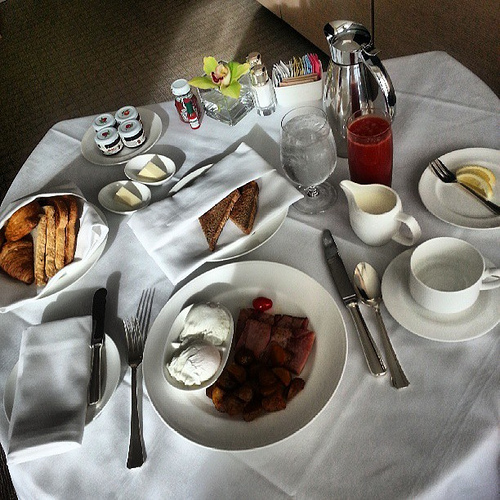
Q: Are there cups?
A: Yes, there is a cup.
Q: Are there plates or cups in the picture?
A: Yes, there is a cup.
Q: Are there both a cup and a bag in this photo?
A: No, there is a cup but no bags.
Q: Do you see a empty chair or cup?
A: Yes, there is an empty cup.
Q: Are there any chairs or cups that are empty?
A: Yes, the cup is empty.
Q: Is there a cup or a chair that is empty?
A: Yes, the cup is empty.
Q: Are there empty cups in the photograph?
A: Yes, there is an empty cup.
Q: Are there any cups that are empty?
A: Yes, there is an empty cup.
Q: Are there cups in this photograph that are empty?
A: Yes, there is a cup that is empty.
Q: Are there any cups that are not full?
A: Yes, there is a empty cup.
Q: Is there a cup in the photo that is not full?
A: Yes, there is a empty cup.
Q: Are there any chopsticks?
A: No, there are no chopsticks.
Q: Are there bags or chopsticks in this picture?
A: No, there are no chopsticks or bags.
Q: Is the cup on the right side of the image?
A: Yes, the cup is on the right of the image.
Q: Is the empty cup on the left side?
A: No, the cup is on the right of the image.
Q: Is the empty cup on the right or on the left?
A: The cup is on the right of the image.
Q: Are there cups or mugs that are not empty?
A: No, there is a cup but it is empty.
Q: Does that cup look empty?
A: Yes, the cup is empty.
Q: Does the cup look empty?
A: Yes, the cup is empty.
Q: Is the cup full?
A: No, the cup is empty.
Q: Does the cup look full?
A: No, the cup is empty.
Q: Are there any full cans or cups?
A: No, there is a cup but it is empty.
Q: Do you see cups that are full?
A: No, there is a cup but it is empty.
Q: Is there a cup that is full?
A: No, there is a cup but it is empty.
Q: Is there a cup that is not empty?
A: No, there is a cup but it is empty.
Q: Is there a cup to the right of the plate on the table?
A: Yes, there is a cup to the right of the plate.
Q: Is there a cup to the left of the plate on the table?
A: No, the cup is to the right of the plate.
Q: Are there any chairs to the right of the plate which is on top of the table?
A: No, there is a cup to the right of the plate.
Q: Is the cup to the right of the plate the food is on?
A: Yes, the cup is to the right of the plate.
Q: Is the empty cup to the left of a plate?
A: No, the cup is to the right of a plate.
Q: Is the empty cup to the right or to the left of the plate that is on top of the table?
A: The cup is to the right of the plate.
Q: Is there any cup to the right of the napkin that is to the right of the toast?
A: Yes, there is a cup to the right of the napkin.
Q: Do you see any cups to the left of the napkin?
A: No, the cup is to the right of the napkin.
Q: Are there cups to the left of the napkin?
A: No, the cup is to the right of the napkin.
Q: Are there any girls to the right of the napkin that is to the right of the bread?
A: No, there is a cup to the right of the napkin.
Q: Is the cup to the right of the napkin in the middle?
A: Yes, the cup is to the right of the napkin.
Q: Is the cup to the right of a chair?
A: No, the cup is to the right of the napkin.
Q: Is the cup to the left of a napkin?
A: No, the cup is to the right of a napkin.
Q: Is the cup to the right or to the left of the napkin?
A: The cup is to the right of the napkin.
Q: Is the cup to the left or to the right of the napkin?
A: The cup is to the right of the napkin.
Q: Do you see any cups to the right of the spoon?
A: Yes, there is a cup to the right of the spoon.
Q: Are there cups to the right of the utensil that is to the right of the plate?
A: Yes, there is a cup to the right of the spoon.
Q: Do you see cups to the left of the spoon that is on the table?
A: No, the cup is to the right of the spoon.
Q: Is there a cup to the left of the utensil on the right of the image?
A: No, the cup is to the right of the spoon.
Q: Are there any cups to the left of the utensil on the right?
A: No, the cup is to the right of the spoon.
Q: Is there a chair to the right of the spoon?
A: No, there is a cup to the right of the spoon.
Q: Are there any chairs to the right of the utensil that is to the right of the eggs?
A: No, there is a cup to the right of the spoon.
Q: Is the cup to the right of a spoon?
A: Yes, the cup is to the right of a spoon.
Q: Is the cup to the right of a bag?
A: No, the cup is to the right of a spoon.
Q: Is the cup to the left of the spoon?
A: No, the cup is to the right of the spoon.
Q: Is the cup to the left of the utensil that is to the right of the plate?
A: No, the cup is to the right of the spoon.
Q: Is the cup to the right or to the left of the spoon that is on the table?
A: The cup is to the right of the spoon.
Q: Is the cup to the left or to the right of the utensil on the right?
A: The cup is to the right of the spoon.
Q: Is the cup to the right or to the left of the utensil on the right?
A: The cup is to the right of the spoon.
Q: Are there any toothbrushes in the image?
A: No, there are no toothbrushes.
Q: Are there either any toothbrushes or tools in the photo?
A: No, there are no toothbrushes or tools.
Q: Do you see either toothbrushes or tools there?
A: No, there are no toothbrushes or tools.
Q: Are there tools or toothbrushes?
A: No, there are no toothbrushes or tools.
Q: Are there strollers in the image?
A: No, there are no strollers.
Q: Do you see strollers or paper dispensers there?
A: No, there are no strollers or paper dispensers.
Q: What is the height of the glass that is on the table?
A: The glass is tall.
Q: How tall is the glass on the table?
A: The glass is tall.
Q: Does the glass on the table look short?
A: No, the glass is tall.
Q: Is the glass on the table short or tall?
A: The glass is tall.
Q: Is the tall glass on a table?
A: Yes, the glass is on a table.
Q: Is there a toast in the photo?
A: Yes, there is a toast.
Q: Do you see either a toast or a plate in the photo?
A: Yes, there is a toast.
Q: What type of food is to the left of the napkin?
A: The food is a toast.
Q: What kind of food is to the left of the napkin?
A: The food is a toast.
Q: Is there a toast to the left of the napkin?
A: Yes, there is a toast to the left of the napkin.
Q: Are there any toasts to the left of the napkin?
A: Yes, there is a toast to the left of the napkin.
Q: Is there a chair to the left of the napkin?
A: No, there is a toast to the left of the napkin.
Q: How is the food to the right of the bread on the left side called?
A: The food is a toast.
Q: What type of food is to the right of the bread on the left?
A: The food is a toast.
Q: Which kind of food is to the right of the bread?
A: The food is a toast.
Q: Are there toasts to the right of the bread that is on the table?
A: Yes, there is a toast to the right of the bread.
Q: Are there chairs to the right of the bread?
A: No, there is a toast to the right of the bread.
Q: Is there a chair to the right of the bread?
A: No, there is a toast to the right of the bread.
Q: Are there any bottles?
A: Yes, there is a bottle.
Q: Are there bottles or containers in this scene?
A: Yes, there is a bottle.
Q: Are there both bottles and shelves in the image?
A: No, there is a bottle but no shelves.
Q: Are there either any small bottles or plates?
A: Yes, there is a small bottle.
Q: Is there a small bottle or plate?
A: Yes, there is a small bottle.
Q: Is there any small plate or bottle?
A: Yes, there is a small bottle.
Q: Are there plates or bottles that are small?
A: Yes, the bottle is small.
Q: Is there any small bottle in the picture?
A: Yes, there is a small bottle.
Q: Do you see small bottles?
A: Yes, there is a small bottle.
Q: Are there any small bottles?
A: Yes, there is a small bottle.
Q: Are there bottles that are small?
A: Yes, there is a bottle that is small.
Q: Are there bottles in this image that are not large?
A: Yes, there is a small bottle.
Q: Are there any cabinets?
A: No, there are no cabinets.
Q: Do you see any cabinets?
A: No, there are no cabinets.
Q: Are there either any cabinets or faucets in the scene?
A: No, there are no cabinets or faucets.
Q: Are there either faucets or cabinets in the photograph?
A: No, there are no cabinets or faucets.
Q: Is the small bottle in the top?
A: Yes, the bottle is in the top of the image.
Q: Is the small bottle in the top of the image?
A: Yes, the bottle is in the top of the image.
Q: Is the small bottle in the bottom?
A: No, the bottle is in the top of the image.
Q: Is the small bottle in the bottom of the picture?
A: No, the bottle is in the top of the image.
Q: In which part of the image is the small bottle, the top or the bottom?
A: The bottle is in the top of the image.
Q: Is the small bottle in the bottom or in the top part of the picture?
A: The bottle is in the top of the image.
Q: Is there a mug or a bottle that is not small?
A: No, there is a bottle but it is small.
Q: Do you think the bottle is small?
A: Yes, the bottle is small.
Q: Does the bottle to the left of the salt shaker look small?
A: Yes, the bottle is small.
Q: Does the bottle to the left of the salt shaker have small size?
A: Yes, the bottle is small.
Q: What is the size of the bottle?
A: The bottle is small.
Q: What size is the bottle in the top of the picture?
A: The bottle is small.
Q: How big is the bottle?
A: The bottle is small.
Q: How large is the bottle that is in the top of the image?
A: The bottle is small.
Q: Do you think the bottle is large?
A: No, the bottle is small.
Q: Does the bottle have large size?
A: No, the bottle is small.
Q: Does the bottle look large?
A: No, the bottle is small.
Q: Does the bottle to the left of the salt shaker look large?
A: No, the bottle is small.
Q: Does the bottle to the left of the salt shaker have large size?
A: No, the bottle is small.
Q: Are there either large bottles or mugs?
A: No, there is a bottle but it is small.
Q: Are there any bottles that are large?
A: No, there is a bottle but it is small.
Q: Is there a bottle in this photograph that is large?
A: No, there is a bottle but it is small.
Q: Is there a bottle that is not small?
A: No, there is a bottle but it is small.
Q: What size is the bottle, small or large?
A: The bottle is small.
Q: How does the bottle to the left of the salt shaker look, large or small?
A: The bottle is small.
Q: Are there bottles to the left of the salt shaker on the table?
A: Yes, there is a bottle to the left of the salt shaker.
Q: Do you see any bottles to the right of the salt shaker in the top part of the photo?
A: No, the bottle is to the left of the salt shaker.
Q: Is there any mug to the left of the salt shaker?
A: No, there is a bottle to the left of the salt shaker.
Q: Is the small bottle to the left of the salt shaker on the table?
A: Yes, the bottle is to the left of the salt shaker.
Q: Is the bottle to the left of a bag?
A: No, the bottle is to the left of the salt shaker.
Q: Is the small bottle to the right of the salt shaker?
A: No, the bottle is to the left of the salt shaker.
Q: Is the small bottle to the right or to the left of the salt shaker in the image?
A: The bottle is to the left of the salt shaker.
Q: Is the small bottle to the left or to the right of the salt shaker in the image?
A: The bottle is to the left of the salt shaker.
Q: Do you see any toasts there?
A: Yes, there is a toast.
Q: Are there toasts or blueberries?
A: Yes, there is a toast.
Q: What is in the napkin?
A: The toast is in the napkin.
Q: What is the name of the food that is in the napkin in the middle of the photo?
A: The food is a toast.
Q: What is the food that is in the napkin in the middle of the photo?
A: The food is a toast.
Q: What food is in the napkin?
A: The food is a toast.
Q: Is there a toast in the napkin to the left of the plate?
A: Yes, there is a toast in the napkin.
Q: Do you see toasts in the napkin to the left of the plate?
A: Yes, there is a toast in the napkin.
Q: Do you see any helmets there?
A: No, there are no helmets.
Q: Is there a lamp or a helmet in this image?
A: No, there are no helmets or lamps.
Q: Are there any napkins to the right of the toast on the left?
A: Yes, there is a napkin to the right of the toast.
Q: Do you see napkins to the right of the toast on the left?
A: Yes, there is a napkin to the right of the toast.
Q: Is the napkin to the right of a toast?
A: Yes, the napkin is to the right of a toast.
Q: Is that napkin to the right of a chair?
A: No, the napkin is to the right of a toast.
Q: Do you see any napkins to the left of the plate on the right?
A: Yes, there is a napkin to the left of the plate.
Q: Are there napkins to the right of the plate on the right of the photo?
A: No, the napkin is to the left of the plate.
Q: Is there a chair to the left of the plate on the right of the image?
A: No, there is a napkin to the left of the plate.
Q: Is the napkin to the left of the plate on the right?
A: Yes, the napkin is to the left of the plate.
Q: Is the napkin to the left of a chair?
A: No, the napkin is to the left of the plate.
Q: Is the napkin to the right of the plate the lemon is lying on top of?
A: No, the napkin is to the left of the plate.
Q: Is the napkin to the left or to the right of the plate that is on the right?
A: The napkin is to the left of the plate.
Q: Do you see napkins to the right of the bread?
A: Yes, there is a napkin to the right of the bread.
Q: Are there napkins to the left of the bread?
A: No, the napkin is to the right of the bread.